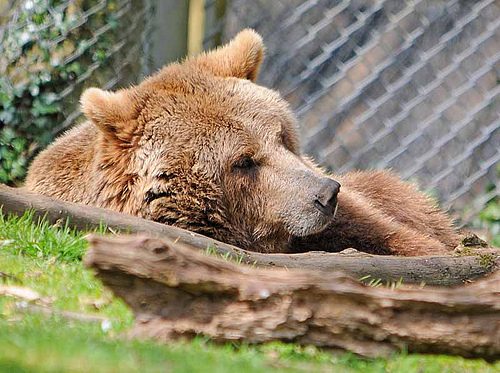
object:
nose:
[312, 176, 340, 215]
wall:
[10, 6, 142, 79]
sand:
[3, 281, 115, 337]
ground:
[0, 215, 497, 373]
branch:
[0, 183, 499, 289]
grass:
[0, 204, 499, 373]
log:
[80, 232, 497, 363]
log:
[0, 182, 499, 289]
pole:
[186, 0, 209, 62]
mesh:
[400, 140, 482, 186]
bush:
[3, 0, 150, 190]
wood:
[83, 234, 498, 359]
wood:
[1, 182, 499, 286]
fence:
[4, 4, 191, 91]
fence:
[212, 0, 489, 205]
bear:
[25, 27, 459, 255]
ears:
[208, 27, 264, 83]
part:
[355, 57, 475, 167]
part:
[322, 182, 341, 217]